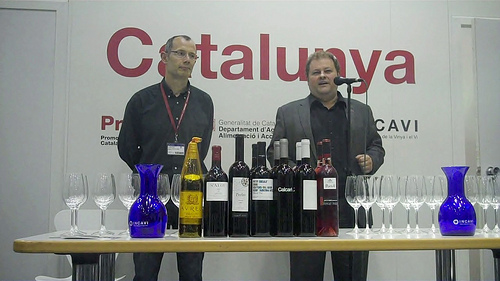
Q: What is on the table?
A: Bottles of wine.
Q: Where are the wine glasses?
A: On the table.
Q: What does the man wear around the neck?
A: Lanyard.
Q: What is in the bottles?
A: Wine.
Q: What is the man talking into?
A: Microphone.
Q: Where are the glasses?
A: On table.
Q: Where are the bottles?
A: On table.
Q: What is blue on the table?
A: Vases.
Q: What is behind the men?
A: Sign.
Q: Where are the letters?
A: On Sign.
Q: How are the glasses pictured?
A: Empty.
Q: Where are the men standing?
A: Behind table.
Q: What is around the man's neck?
A: Lanyard.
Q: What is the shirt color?
A: Black.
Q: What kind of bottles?
A: Wine.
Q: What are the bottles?
A: Wine.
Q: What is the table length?
A: Long.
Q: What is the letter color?
A: Red.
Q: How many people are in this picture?
A: Two.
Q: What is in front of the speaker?
A: A microphone.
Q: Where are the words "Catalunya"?
A: On the wall.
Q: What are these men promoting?
A: Wine.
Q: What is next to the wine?
A: Wine glasses.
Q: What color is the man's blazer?
A: Grey.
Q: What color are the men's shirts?
A: Black.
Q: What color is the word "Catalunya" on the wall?
A: Red.